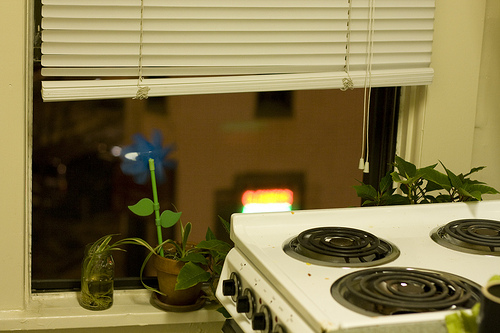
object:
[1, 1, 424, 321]
window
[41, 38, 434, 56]
mini blinds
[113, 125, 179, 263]
flower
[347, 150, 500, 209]
plant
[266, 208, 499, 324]
three burners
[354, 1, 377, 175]
strings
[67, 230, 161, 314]
plant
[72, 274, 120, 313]
water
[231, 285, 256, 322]
knobs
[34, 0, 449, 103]
blinds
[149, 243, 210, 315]
pot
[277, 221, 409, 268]
burners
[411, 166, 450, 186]
green leaves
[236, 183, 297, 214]
sign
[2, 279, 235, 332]
window sill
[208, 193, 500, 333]
electric range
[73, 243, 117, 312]
glass